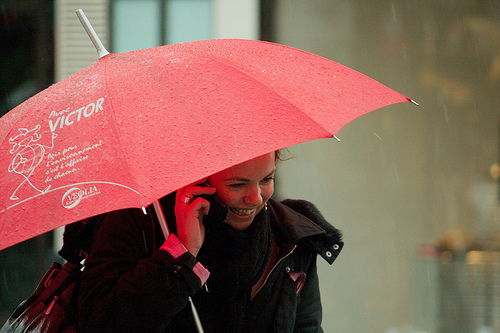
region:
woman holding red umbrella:
[15, 35, 390, 328]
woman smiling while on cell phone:
[174, 130, 291, 234]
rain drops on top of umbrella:
[163, 68, 223, 165]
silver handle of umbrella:
[145, 171, 170, 253]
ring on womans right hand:
[175, 188, 195, 211]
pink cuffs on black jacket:
[141, 224, 206, 276]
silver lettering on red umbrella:
[7, 80, 119, 226]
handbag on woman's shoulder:
[14, 235, 131, 330]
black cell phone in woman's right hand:
[191, 170, 229, 220]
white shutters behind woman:
[52, 22, 124, 95]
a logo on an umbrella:
[0, 111, 118, 224]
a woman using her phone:
[94, 147, 363, 331]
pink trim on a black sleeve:
[161, 237, 185, 249]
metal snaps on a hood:
[323, 236, 335, 260]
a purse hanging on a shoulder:
[11, 246, 80, 330]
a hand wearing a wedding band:
[171, 187, 210, 249]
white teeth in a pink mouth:
[232, 206, 254, 216]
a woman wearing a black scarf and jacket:
[211, 140, 272, 285]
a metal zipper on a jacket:
[279, 246, 294, 268]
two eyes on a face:
[226, 177, 275, 188]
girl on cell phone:
[81, 147, 331, 330]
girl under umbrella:
[81, 152, 336, 331]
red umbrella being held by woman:
[0, 4, 425, 255]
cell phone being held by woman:
[195, 178, 227, 225]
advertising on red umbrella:
[6, 96, 133, 209]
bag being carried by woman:
[2, 240, 84, 332]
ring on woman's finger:
[178, 190, 193, 203]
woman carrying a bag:
[69, 141, 327, 331]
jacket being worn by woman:
[83, 222, 343, 330]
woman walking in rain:
[63, 139, 330, 331]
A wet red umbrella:
[132, 49, 286, 135]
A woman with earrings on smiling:
[218, 158, 281, 228]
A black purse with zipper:
[10, 253, 68, 329]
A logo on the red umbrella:
[12, 97, 128, 214]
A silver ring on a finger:
[170, 190, 203, 210]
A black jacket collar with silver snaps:
[281, 195, 346, 266]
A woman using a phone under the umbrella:
[145, 136, 300, 266]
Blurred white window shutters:
[51, 10, 79, 68]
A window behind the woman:
[107, 3, 237, 33]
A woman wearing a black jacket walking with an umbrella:
[12, 69, 349, 323]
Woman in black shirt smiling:
[226, 164, 274, 254]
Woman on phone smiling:
[181, 151, 283, 248]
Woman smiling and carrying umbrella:
[157, 87, 294, 255]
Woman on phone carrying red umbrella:
[161, 99, 284, 270]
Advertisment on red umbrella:
[11, 100, 126, 210]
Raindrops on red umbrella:
[138, 67, 230, 149]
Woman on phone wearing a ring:
[166, 157, 287, 248]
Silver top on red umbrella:
[58, 5, 135, 79]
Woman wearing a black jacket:
[211, 155, 292, 331]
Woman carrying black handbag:
[10, 230, 108, 331]